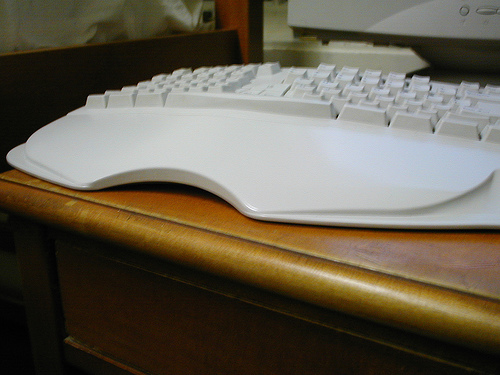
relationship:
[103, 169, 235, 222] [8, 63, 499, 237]
curve under keyboard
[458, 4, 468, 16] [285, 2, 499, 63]
button on monitor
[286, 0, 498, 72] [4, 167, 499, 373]
monitor on desk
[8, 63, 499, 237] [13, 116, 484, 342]
keyboard on desk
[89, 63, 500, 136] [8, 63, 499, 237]
key on keyboard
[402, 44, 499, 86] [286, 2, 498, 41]
base of monitor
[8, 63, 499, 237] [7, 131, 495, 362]
keyboard on desk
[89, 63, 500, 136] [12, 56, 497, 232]
key on board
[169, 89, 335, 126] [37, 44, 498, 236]
key on key board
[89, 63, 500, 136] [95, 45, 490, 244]
key on keyboard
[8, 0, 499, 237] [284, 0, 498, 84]
keyboard by computer monitor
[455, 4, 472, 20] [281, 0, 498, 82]
button on monitor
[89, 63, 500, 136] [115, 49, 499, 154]
key on keyboard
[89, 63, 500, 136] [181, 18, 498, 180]
key on keyboard